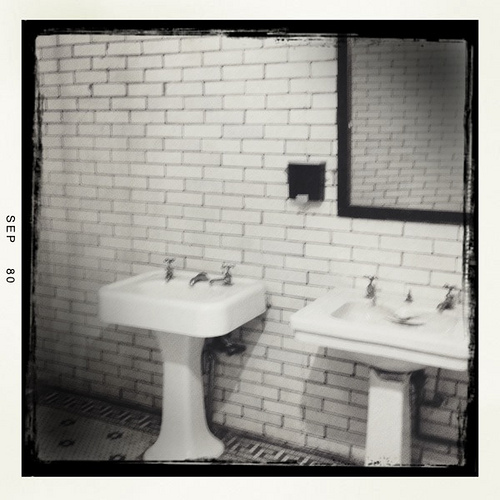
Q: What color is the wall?
A: Gray.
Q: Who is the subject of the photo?
A: The sinks.